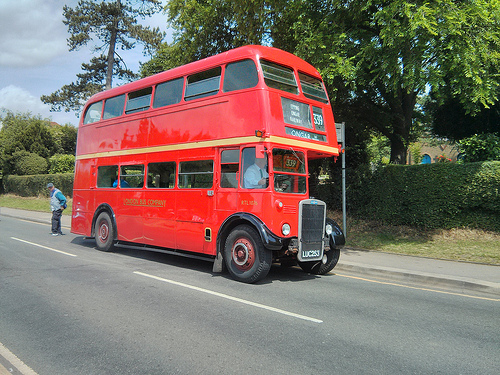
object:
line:
[132, 271, 323, 324]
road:
[0, 205, 500, 375]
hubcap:
[230, 236, 256, 272]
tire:
[94, 211, 114, 252]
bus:
[69, 42, 349, 286]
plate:
[301, 248, 322, 260]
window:
[176, 159, 213, 189]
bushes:
[387, 162, 463, 230]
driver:
[243, 147, 269, 189]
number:
[313, 113, 318, 125]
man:
[46, 182, 67, 236]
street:
[0, 214, 500, 375]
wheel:
[223, 223, 273, 284]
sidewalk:
[337, 246, 500, 295]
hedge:
[345, 159, 500, 235]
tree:
[266, 0, 500, 166]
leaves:
[461, 3, 499, 41]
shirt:
[49, 188, 67, 213]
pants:
[51, 208, 64, 234]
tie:
[259, 168, 267, 188]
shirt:
[112, 179, 131, 188]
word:
[162, 199, 166, 207]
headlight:
[280, 222, 291, 237]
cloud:
[11, 21, 52, 88]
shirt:
[242, 163, 269, 189]